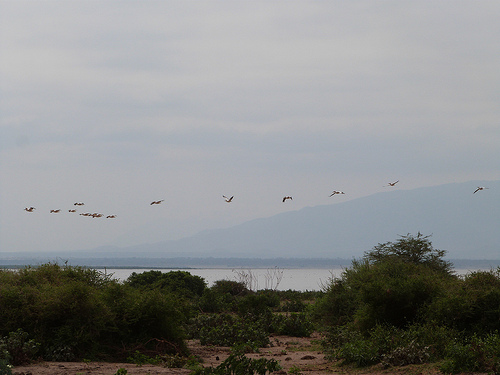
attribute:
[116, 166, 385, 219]
birds — close, flying, high, soaring, white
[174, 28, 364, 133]
sky — dark, damp, grey, cloudy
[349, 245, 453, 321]
bush — close, small, dark, green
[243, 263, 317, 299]
water — calm, far, blue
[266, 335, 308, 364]
sand — brown, dirty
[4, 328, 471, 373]
dirt — sandy